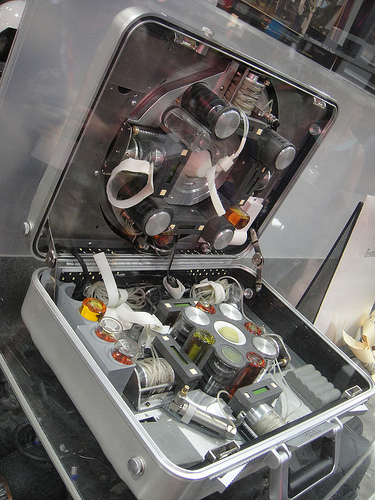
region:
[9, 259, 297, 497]
a silver metal suitcase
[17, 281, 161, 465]
a silver metal suitcase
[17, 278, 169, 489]
the suitcase is gray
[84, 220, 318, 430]
a bunch of mechanics and wires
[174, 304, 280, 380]
a bunch of cylinder pieces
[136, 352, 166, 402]
a bunch of wire pieces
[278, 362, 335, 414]
a bunch of circular pieces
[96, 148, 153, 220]
a bunch of taped pieces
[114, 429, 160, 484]
a bunch of silver pieces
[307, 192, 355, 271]
a shiny white board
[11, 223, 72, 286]
a hinge for a briefcase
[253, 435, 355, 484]
the handle for a briefcase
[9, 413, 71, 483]
a black wire all tangled up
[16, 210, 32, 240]
bolt of a steel case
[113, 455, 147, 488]
bolt of a steel case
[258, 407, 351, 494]
handles of a steel case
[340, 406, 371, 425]
lever of a steel case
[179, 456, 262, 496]
lever of a steel case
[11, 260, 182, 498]
side of a steel case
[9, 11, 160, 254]
side of a steel case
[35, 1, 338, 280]
cover of a steel case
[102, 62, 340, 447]
bio mechanical inside steel case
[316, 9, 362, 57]
reflections of a window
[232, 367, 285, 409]
small electrical computer part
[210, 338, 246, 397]
small electrical computer part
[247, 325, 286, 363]
small electrical computer part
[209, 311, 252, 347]
small electrical computer part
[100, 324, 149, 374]
small electrical computer part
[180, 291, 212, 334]
small electrical computer part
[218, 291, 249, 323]
small electrical computer part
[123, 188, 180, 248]
small electrical computer part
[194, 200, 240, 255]
small electrical computer part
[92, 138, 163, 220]
small electrical computer part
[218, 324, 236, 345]
A clear container in a machine.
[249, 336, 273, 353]
A clear container in a machine.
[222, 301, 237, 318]
A clear container in a machine.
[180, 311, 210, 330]
A clear container in a machine.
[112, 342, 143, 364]
A clear container in a machine.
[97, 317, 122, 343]
A clear container in a machine.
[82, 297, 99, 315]
A clear container in a machine.